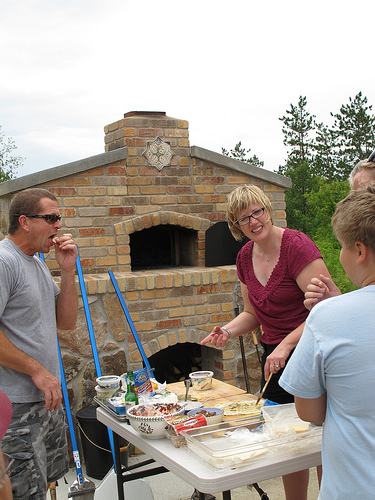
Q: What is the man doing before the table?
A: Eating.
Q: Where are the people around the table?
A: Backyard.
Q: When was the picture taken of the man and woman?
A: Outside Barbecue.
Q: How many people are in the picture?
A: 4.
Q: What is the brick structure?
A: Barbecue pit.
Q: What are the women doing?
A: Talking about the food.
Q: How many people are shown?
A: 4.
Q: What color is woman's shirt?
A: Red.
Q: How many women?
A: 1.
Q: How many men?
A: 3.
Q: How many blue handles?
A: 3.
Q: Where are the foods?
A: On table.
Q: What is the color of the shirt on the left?
A: Grey.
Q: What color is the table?
A: White.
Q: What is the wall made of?
A: Bricks.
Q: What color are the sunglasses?
A: Black.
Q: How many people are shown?
A: 4.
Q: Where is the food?
A: On table.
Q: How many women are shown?
A: 1.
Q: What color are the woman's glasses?
A: Black.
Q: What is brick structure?
A: Fireplace.